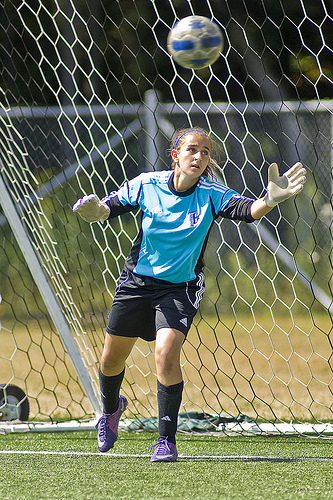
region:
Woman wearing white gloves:
[71, 122, 306, 462]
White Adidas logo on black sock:
[160, 413, 171, 421]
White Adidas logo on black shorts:
[177, 313, 191, 329]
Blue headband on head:
[174, 128, 210, 146]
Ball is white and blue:
[166, 13, 225, 71]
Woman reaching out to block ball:
[70, 124, 306, 466]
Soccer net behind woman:
[0, 0, 332, 447]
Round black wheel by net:
[0, 377, 33, 421]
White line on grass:
[0, 443, 332, 459]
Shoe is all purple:
[148, 433, 184, 464]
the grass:
[176, 462, 220, 493]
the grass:
[210, 475, 231, 497]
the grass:
[221, 480, 235, 497]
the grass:
[219, 455, 247, 489]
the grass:
[212, 454, 235, 493]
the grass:
[211, 463, 225, 488]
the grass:
[199, 438, 227, 490]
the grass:
[196, 462, 224, 498]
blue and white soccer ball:
[164, 14, 225, 69]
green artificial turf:
[1, 429, 331, 497]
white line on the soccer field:
[1, 447, 332, 462]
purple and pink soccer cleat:
[94, 395, 130, 454]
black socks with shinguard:
[151, 378, 186, 441]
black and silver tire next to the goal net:
[1, 381, 32, 425]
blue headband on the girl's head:
[174, 127, 211, 146]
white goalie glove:
[263, 160, 307, 208]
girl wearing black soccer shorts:
[103, 265, 206, 341]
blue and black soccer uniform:
[99, 170, 257, 283]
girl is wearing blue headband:
[164, 127, 251, 154]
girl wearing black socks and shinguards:
[96, 358, 201, 445]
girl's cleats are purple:
[72, 398, 188, 474]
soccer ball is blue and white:
[185, 14, 253, 79]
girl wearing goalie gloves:
[17, 126, 328, 247]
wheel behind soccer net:
[2, 380, 30, 430]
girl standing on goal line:
[47, 435, 332, 466]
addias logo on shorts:
[174, 317, 217, 343]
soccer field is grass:
[56, 442, 280, 491]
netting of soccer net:
[240, 267, 312, 403]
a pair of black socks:
[75, 367, 225, 455]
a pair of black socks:
[87, 356, 293, 497]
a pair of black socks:
[124, 379, 240, 497]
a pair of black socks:
[63, 333, 206, 485]